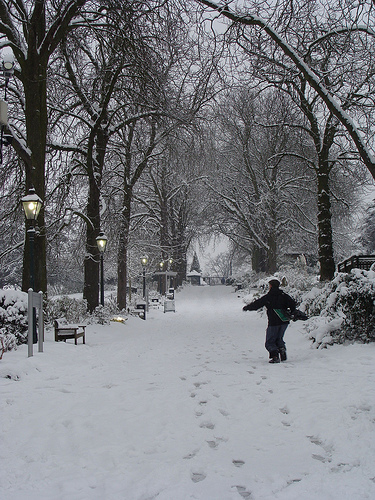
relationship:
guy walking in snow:
[239, 278, 305, 363] [1, 283, 372, 498]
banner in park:
[25, 286, 45, 359] [1, 3, 368, 494]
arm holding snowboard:
[279, 289, 304, 308] [269, 305, 309, 325]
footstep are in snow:
[188, 463, 207, 484] [1, 283, 372, 498]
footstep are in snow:
[196, 395, 211, 410] [1, 283, 372, 498]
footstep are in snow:
[229, 452, 247, 471] [1, 283, 372, 498]